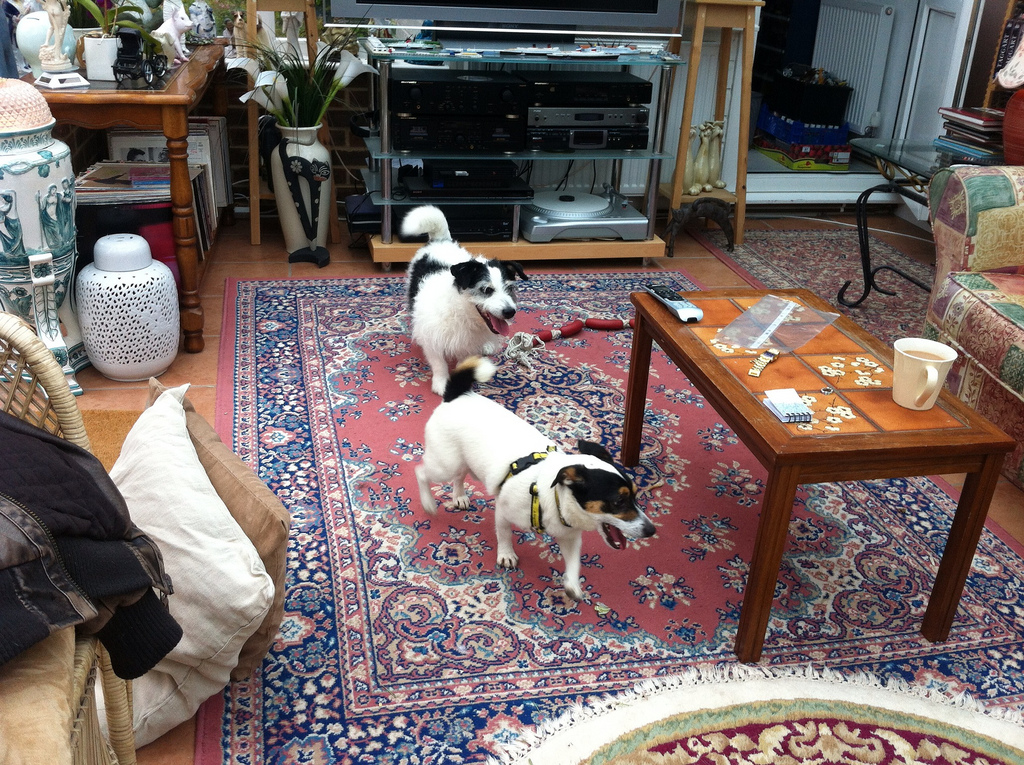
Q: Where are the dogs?
A: In the middle of the room.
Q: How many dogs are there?
A: 2.